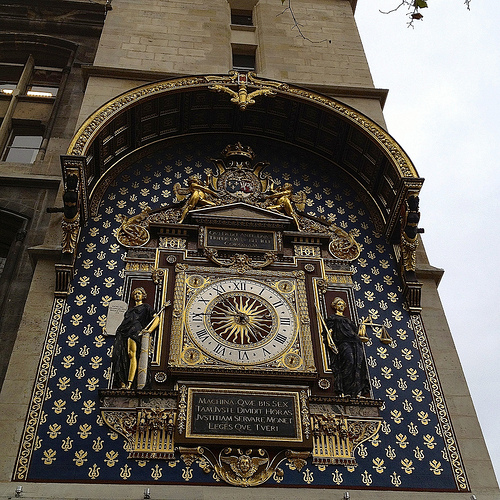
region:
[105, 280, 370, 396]
two statutes of women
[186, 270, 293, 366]
clock face with roman numerals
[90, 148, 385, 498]
ornate clock on building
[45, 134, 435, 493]
blue background with gold accents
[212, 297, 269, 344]
gold accent on red background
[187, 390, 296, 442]
black plaque attached to clock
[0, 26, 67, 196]
windows on building beside clock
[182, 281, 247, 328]
black clock hands on clock face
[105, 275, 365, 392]
statutes wearing black robes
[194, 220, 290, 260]
black plaque above clock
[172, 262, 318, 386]
Clock on side of building.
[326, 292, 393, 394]
Statue of a man holding scale in his hands.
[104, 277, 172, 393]
Statue of a man holding tablet and septor.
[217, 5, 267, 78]
Windows in the building.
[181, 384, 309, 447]
Plaque on side of the building.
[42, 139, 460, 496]
Ornate blue and gold design on side of building.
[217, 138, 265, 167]
Crown on side of building.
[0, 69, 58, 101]
Light inside the building.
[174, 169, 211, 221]
Gold colored statue on building.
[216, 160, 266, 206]
Crest on the side of the building.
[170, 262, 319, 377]
a clock on the side of a building.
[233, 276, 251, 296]
roman numerals on a clock.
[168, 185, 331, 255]
a sculpture on a building.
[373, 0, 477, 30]
a tree branch with leaves.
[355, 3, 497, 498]
a section of a cloudy sky.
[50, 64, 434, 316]
an arch on a building.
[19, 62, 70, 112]
a window on a building.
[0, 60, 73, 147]
a window on a clock tower.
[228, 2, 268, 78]
A window on a clock tower.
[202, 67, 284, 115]
a golden bird.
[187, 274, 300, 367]
a roman clock gothic style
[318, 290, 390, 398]
a human figure symbolizing justice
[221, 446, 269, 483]
a figure representing a little angel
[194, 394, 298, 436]
sign written in latin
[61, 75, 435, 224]
half arch covering the clock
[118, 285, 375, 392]
a pair of human figures on both sides of the clock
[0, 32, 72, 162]
part of the building's window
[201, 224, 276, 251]
illegible sign written in latin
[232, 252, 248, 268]
a figure in form of a human head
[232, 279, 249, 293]
the number twelve in latin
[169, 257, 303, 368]
clock is on wall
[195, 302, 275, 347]
clock uses roman numerals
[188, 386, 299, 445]
inscription located under clock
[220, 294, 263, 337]
black hands on clock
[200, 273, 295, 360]
solar image on clock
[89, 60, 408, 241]
archway located on clock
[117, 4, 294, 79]
light brown bricks above clock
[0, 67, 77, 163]
windows on brown wall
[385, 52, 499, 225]
light grey and cloudy sky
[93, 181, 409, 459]
dark blue background around clock